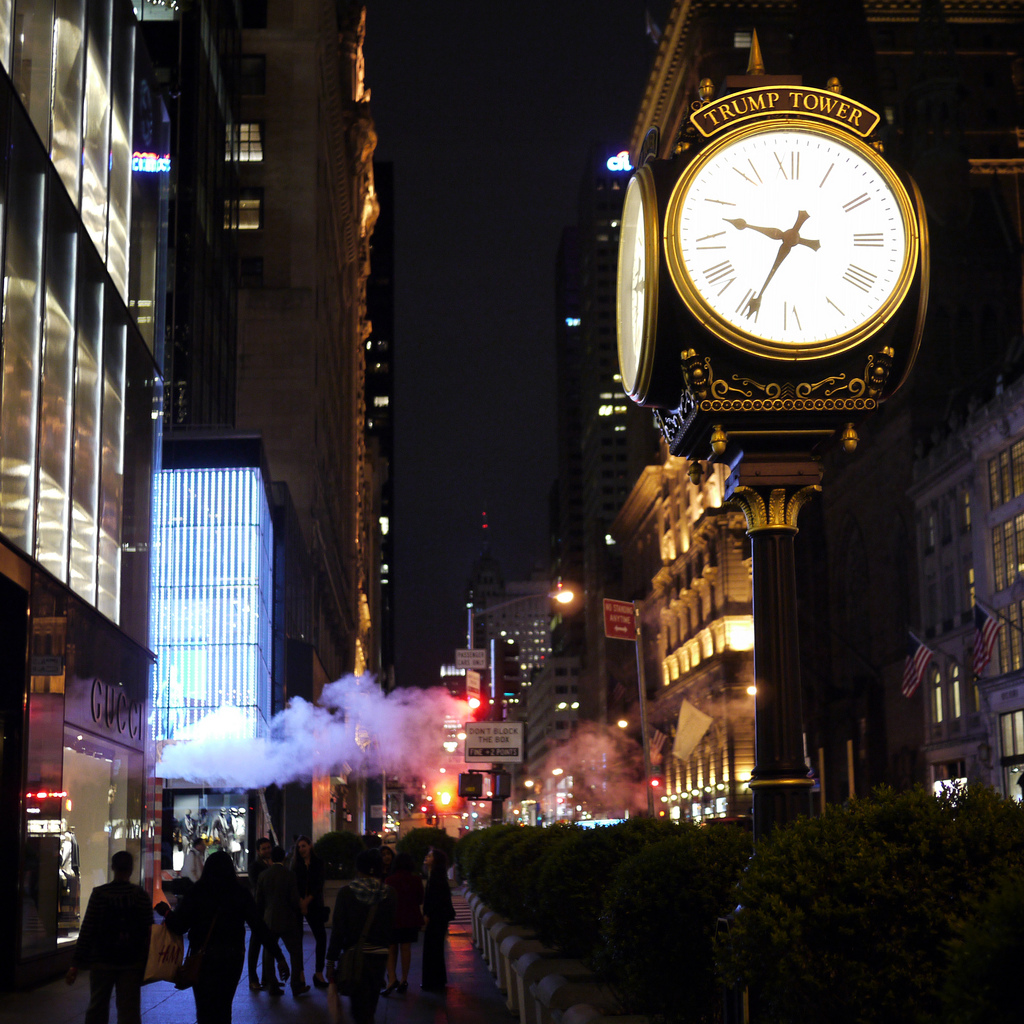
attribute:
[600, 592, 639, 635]
parking sign — red, white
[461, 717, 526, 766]
sign — white, black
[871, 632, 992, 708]
flag — american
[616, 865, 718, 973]
leaves — green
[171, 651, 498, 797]
steam — coming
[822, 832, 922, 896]
leaves — green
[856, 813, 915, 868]
leaves — green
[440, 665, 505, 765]
light — red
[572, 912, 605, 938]
leaves — green